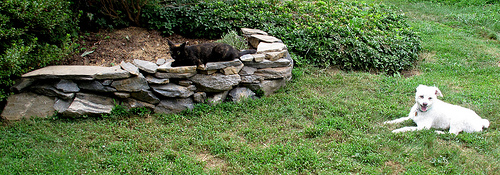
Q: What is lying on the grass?
A: Dog.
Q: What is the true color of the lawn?
A: Green.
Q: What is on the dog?
A: A collar.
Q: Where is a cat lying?
A: Stone wall.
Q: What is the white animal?
A: Dog.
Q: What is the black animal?
A: Cat.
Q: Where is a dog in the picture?
A: On grass.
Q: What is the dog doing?
A: Lying on grass.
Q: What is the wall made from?
A: Rocks.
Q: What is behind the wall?
A: Dirt.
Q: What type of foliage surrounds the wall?
A: Bushes.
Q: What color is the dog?
A: White.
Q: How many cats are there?
A: One.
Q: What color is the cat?
A: Black.